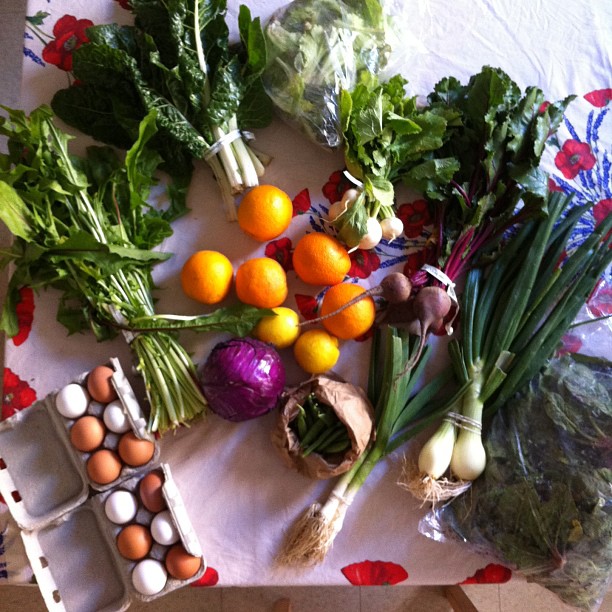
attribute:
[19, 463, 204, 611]
egg carton — open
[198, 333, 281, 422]
onion — Large , red 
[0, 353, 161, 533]
egg carton — open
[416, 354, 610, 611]
herbs — packed, fresh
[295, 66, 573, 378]
vegetable — green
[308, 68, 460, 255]
vegetable — green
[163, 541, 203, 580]
egg — brown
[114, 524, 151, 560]
egg — brown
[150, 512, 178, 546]
egg — white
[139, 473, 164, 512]
egg — brown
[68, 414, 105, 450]
egg — brown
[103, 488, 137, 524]
egg — white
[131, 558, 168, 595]
egg — white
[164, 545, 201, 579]
egg — brown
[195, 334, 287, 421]
onion — large, red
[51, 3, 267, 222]
vegetable — fresh, leafy, bunched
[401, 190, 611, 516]
vegetable — green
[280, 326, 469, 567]
vegetable — green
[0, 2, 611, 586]
table cloth — red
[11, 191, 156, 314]
vegetable — green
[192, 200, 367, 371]
oranges — small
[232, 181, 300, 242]
orange — small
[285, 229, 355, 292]
orange — small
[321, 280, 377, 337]
orange — small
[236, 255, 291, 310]
orange — small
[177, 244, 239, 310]
orange — small